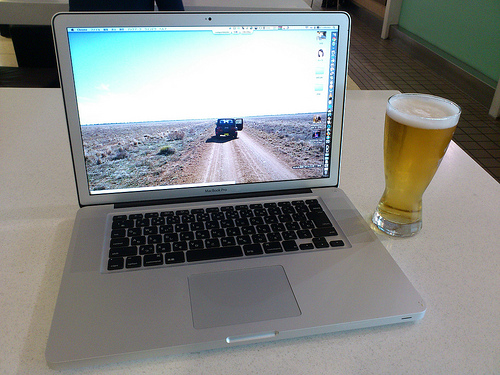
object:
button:
[299, 243, 314, 250]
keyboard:
[107, 198, 346, 271]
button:
[147, 234, 162, 245]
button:
[186, 245, 243, 261]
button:
[107, 258, 124, 270]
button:
[110, 237, 129, 248]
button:
[285, 221, 300, 230]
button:
[267, 232, 283, 241]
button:
[196, 213, 210, 222]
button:
[211, 212, 225, 221]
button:
[240, 209, 254, 217]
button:
[139, 245, 154, 255]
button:
[251, 233, 267, 243]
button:
[282, 240, 299, 252]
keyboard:
[44, 8, 428, 369]